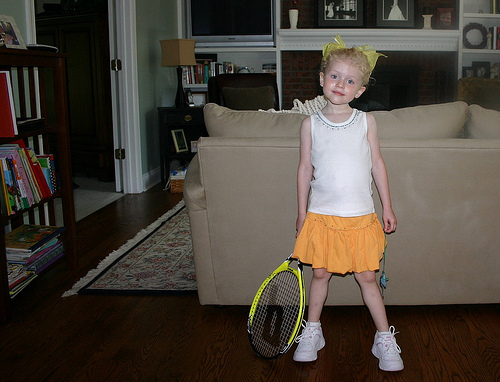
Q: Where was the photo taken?
A: In a living room.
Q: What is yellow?
A: Girl's skirt.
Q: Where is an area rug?
A: On the floor.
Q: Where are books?
A: On shelves.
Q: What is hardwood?
A: Floor.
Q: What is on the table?
A: Lamp.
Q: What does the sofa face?
A: Fireplace.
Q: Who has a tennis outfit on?
A: Little girl.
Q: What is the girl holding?
A: Racquet.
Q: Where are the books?
A: Shelf.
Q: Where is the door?
A: Is the back.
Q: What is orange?
A: Skirt.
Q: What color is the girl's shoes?
A: White.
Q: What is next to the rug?
A: Bookshelf.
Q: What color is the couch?
A: Tan.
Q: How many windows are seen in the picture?
A: One.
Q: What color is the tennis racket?
A: Black and Yellow.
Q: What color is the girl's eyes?
A: Blue.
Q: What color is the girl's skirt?
A: Orange.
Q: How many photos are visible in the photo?
A: Five.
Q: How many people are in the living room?
A: One.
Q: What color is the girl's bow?
A: Yellow.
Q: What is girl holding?
A: Racket.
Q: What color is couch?
A: Tan.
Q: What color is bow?
A: Yellow.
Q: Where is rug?
A: Living room.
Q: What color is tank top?
A: White.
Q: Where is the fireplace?
A: Living room.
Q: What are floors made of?
A: Wood.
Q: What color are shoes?
A: White.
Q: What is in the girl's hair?
A: A bow.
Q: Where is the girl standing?
A: Living room.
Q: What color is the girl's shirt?
A: White.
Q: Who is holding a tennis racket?
A: Little girl.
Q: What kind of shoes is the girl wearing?
A: Tennis shoes.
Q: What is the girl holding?
A: Tennis racket.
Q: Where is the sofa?
A: Behind the girl.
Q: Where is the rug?
A: On the wood floor.